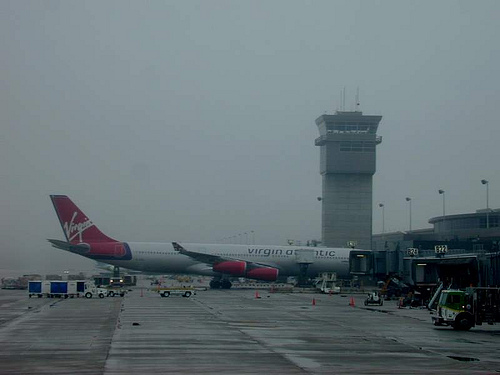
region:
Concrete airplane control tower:
[305, 78, 399, 274]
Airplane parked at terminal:
[39, 184, 394, 292]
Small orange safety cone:
[306, 290, 318, 313]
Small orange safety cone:
[251, 286, 263, 303]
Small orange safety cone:
[344, 292, 359, 311]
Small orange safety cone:
[135, 281, 148, 304]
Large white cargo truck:
[20, 270, 119, 310]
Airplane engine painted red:
[205, 249, 254, 284]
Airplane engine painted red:
[240, 264, 285, 286]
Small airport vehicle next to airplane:
[360, 283, 387, 311]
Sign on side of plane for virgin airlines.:
[241, 245, 343, 258]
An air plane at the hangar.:
[27, 150, 480, 342]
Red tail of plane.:
[145, 272, 201, 324]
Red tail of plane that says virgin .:
[21, 175, 104, 296]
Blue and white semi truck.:
[0, 267, 125, 313]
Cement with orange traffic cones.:
[237, 286, 359, 326]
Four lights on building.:
[357, 160, 487, 246]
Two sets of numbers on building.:
[380, 228, 460, 273]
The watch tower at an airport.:
[275, 23, 395, 263]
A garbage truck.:
[401, 275, 498, 345]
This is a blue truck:
[6, 271, 128, 316]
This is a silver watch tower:
[281, 83, 421, 251]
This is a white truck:
[392, 257, 499, 369]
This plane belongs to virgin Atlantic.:
[213, 221, 395, 291]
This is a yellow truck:
[144, 276, 234, 327]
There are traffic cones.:
[249, 284, 397, 344]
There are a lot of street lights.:
[346, 157, 498, 332]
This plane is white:
[27, 142, 461, 324]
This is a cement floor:
[22, 273, 409, 373]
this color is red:
[50, 192, 144, 292]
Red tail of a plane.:
[46, 167, 148, 277]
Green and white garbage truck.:
[410, 266, 491, 354]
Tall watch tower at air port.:
[279, 102, 394, 257]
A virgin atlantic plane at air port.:
[0, 175, 450, 331]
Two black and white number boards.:
[383, 229, 451, 285]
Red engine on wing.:
[152, 250, 311, 317]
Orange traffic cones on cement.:
[235, 285, 362, 345]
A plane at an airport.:
[8, 110, 473, 365]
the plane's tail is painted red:
[47, 190, 130, 262]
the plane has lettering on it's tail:
[61, 212, 96, 240]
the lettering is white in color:
[60, 212, 95, 239]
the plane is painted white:
[97, 239, 374, 281]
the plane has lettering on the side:
[246, 243, 338, 259]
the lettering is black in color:
[245, 245, 335, 258]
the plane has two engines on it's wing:
[210, 259, 279, 284]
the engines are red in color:
[211, 257, 281, 282]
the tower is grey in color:
[310, 105, 380, 240]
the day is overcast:
[2, 1, 496, 371]